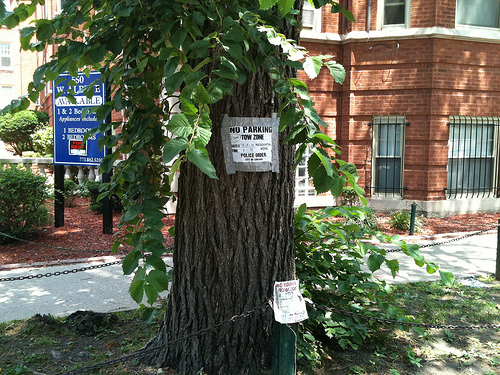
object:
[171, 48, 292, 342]
trunk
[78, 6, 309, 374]
tree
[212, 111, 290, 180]
sign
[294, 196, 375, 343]
bush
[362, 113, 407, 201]
window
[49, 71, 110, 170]
sign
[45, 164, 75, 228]
stick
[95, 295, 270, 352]
chain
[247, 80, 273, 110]
bark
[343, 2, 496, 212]
build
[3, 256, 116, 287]
chain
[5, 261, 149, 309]
sidewalk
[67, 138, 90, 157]
sign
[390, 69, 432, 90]
red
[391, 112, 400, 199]
bars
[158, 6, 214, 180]
foliage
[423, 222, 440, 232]
gravel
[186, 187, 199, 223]
grooves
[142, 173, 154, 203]
leaves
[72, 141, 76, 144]
words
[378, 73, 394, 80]
bricks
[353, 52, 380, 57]
wall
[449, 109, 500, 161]
windows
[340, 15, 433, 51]
lines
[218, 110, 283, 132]
tape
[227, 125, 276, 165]
no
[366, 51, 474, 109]
shade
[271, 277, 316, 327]
poster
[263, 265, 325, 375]
low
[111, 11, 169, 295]
branches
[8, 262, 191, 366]
fence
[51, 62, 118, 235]
housing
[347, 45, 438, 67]
rows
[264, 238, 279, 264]
texture